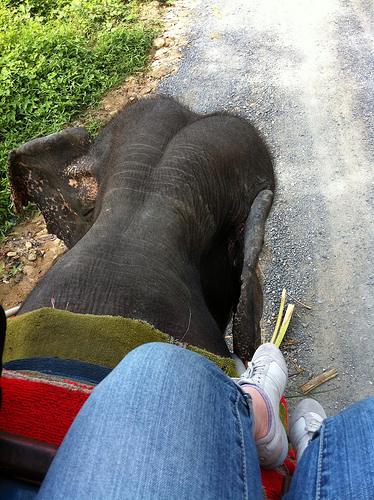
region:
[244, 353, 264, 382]
Shoelaces on the person's left foot.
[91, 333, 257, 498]
Left pant leg of the person.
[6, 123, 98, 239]
Left ear of the elephant.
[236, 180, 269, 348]
Right ear of the elephant.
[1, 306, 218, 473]
Green, blue and red rug on the elephant.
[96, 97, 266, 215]
Back of the head of the elephant.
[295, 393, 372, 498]
Right pant leg of the person sitting on the elephant.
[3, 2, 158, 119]
Grass in the left hand corner.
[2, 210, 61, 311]
Dirt to the left of the elephant.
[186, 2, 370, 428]
Gravel road in front of the elephant.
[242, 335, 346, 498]
white tennis shoes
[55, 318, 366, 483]
person wearing blue jeans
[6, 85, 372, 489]
person riding on an elephant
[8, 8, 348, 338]
elephant walking down a road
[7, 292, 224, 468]
green, blue, and red blanket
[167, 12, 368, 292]
dirt and gravel road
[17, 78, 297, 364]
grey elephant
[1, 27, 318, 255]
grass on the side of the road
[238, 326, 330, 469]
pair of tennis shoes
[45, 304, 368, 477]
person sitting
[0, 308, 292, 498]
colorful rug on elephants back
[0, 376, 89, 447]
red stripe on rug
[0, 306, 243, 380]
green stripe on rug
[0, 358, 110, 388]
blue stripe on rug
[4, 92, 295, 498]
a big gray elephant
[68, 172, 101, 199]
a light colored area behind the elephant's ear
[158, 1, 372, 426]
elephant on gray gravel road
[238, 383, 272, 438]
bare ankle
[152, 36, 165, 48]
rock beside road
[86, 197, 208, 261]
back of the elephant's neck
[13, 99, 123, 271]
The huge elephant ear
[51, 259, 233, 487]
Woman riding on the back of an elephant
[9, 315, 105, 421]
Colorful blanket on elephants back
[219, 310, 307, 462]
Woman's white tennis shoes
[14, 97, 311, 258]
Elephant's large head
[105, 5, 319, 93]
Gravel trail for elephant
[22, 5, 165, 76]
Grass on side of trail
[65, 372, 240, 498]
Womans leg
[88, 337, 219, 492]
Woman is wearing jeans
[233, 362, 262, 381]
Shoelaces on woman's shoe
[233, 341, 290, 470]
shoe on foot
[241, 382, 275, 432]
the low cut sock is gray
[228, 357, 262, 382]
white shoelaces on shoes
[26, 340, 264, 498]
blue denim jeans on leg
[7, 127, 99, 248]
the elephants ear is big and gray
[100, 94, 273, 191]
there are two bumps on the top of the elephants head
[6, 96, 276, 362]
the elephant has wrinkly skin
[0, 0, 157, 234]
there is vegetation growing next to the road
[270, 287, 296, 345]
there are pieces of straw on the road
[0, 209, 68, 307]
there is brown sand next to the road